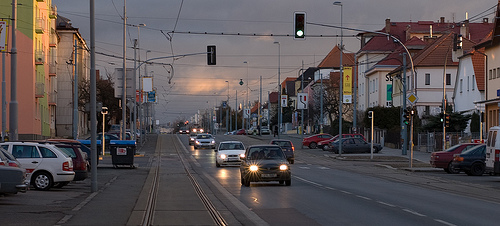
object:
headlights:
[246, 164, 260, 173]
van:
[482, 124, 500, 170]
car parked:
[429, 143, 478, 173]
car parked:
[301, 134, 338, 150]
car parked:
[33, 138, 88, 184]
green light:
[290, 30, 308, 38]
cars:
[267, 139, 294, 166]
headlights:
[279, 165, 288, 173]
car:
[239, 144, 292, 186]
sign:
[341, 64, 354, 102]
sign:
[404, 89, 419, 106]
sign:
[295, 93, 308, 110]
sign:
[280, 95, 289, 108]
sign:
[141, 76, 155, 92]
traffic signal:
[293, 13, 305, 40]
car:
[213, 140, 246, 167]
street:
[139, 162, 206, 205]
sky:
[217, 5, 313, 39]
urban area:
[108, 65, 315, 210]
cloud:
[189, 71, 222, 100]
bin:
[107, 139, 135, 167]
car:
[0, 141, 73, 190]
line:
[356, 193, 369, 201]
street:
[299, 162, 346, 224]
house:
[451, 49, 483, 139]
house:
[394, 32, 454, 132]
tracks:
[131, 167, 199, 216]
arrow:
[345, 74, 350, 80]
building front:
[4, 8, 62, 149]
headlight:
[220, 153, 227, 159]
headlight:
[238, 152, 245, 158]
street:
[366, 177, 456, 223]